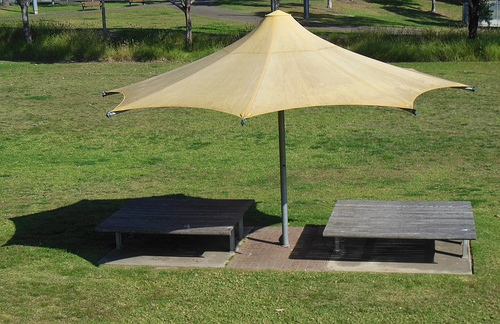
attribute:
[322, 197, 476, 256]
platform — Wooden 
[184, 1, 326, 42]
road — paved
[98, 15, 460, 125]
umbrella — Tan , yellow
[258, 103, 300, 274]
pole — metal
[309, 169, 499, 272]
table — wood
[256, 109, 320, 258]
pole — grey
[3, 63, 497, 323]
grass — healthy, brown, green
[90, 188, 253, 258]
table — wooden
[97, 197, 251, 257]
table — shaded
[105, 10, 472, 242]
umbrella — off white, large, yellow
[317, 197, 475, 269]
table — wooden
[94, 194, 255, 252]
table — wooden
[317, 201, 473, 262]
table — wooden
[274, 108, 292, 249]
post — metallic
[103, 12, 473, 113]
umbrella — yellow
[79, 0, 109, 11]
bench — wood